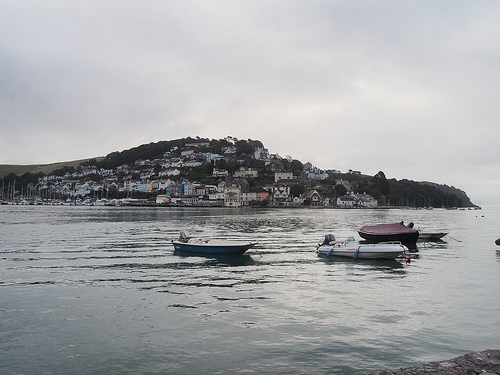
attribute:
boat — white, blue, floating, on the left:
[169, 232, 252, 257]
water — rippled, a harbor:
[2, 204, 497, 372]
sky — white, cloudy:
[0, 2, 499, 202]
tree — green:
[50, 165, 63, 178]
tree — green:
[57, 166, 68, 179]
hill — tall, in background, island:
[3, 135, 470, 210]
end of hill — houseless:
[350, 168, 476, 209]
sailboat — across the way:
[19, 182, 34, 205]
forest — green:
[364, 170, 457, 209]